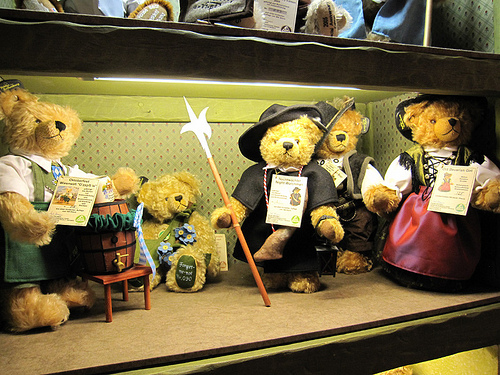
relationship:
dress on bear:
[381, 145, 483, 281] [372, 90, 484, 317]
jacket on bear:
[231, 165, 351, 263] [224, 100, 339, 288]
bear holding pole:
[0, 85, 139, 332] [178, 95, 274, 308]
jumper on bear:
[0, 156, 80, 286] [2, 86, 95, 330]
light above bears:
[44, 68, 384, 111] [240, 96, 397, 288]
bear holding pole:
[234, 102, 344, 297] [180, 95, 271, 306]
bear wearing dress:
[396, 101, 477, 279] [381, 145, 483, 281]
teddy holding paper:
[0, 88, 142, 336] [43, 172, 101, 229]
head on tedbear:
[253, 115, 322, 165] [209, 102, 344, 292]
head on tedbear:
[136, 168, 198, 223] [135, 170, 218, 294]